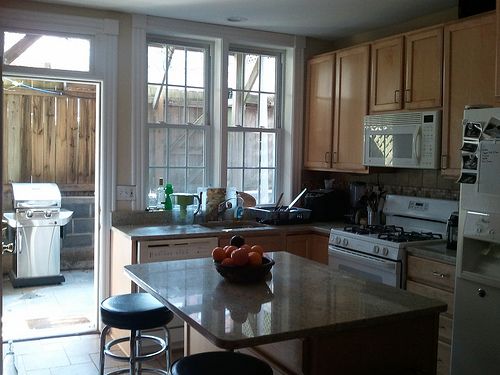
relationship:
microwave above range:
[355, 108, 442, 171] [325, 192, 460, 291]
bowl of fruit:
[213, 258, 271, 283] [206, 234, 268, 265]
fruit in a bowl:
[206, 234, 268, 265] [213, 258, 271, 283]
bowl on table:
[213, 258, 271, 283] [120, 247, 450, 353]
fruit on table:
[206, 234, 268, 265] [120, 247, 450, 353]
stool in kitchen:
[97, 291, 172, 374] [2, 0, 499, 374]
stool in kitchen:
[172, 347, 270, 373] [2, 0, 499, 374]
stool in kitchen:
[172, 347, 274, 375] [2, 0, 499, 374]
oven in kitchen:
[328, 193, 458, 289] [2, 0, 499, 374]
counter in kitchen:
[111, 213, 343, 244] [2, 0, 499, 374]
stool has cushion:
[97, 291, 172, 374] [98, 289, 174, 329]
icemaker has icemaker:
[448, 103, 499, 374] [463, 210, 499, 275]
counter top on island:
[124, 248, 448, 351] [181, 313, 446, 374]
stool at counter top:
[97, 291, 172, 374] [124, 248, 448, 351]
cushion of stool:
[98, 289, 174, 329] [97, 291, 172, 374]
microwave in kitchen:
[355, 108, 442, 171] [2, 0, 499, 374]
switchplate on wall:
[113, 183, 140, 205] [1, 0, 303, 331]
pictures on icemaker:
[460, 115, 499, 186] [448, 103, 499, 374]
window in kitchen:
[140, 26, 294, 214] [2, 0, 499, 374]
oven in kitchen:
[328, 246, 402, 292] [2, 0, 499, 374]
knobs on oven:
[330, 233, 393, 262] [328, 246, 402, 292]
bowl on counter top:
[213, 258, 271, 283] [124, 248, 448, 351]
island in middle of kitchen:
[181, 313, 446, 374] [2, 0, 499, 374]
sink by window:
[195, 214, 273, 233] [140, 26, 294, 214]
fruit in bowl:
[206, 234, 268, 265] [213, 258, 271, 283]